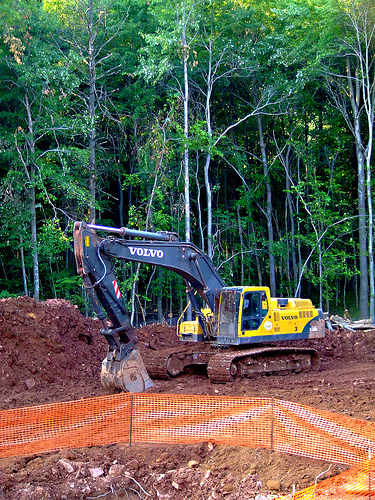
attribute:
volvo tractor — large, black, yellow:
[71, 220, 326, 393]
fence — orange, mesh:
[0, 388, 362, 498]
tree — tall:
[133, 1, 204, 320]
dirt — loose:
[1, 293, 361, 409]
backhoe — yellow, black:
[70, 219, 326, 392]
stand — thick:
[1, 2, 363, 326]